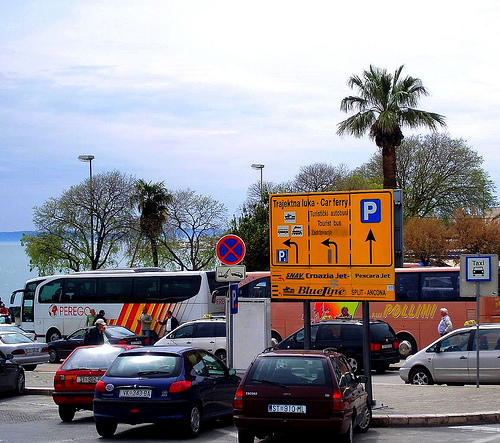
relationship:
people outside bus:
[67, 303, 186, 362] [9, 251, 231, 359]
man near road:
[77, 300, 118, 379] [0, 388, 473, 438]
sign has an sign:
[188, 220, 258, 270] [215, 232, 247, 264]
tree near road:
[129, 161, 184, 272] [0, 379, 494, 428]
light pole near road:
[39, 123, 134, 292] [19, 363, 463, 440]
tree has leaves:
[319, 46, 460, 236] [329, 66, 455, 145]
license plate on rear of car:
[240, 387, 329, 436] [220, 322, 383, 441]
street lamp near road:
[55, 134, 129, 304] [7, 346, 485, 441]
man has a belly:
[415, 292, 463, 351] [429, 270, 460, 369]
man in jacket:
[154, 305, 182, 341] [159, 315, 179, 330]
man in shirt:
[154, 305, 182, 341] [162, 315, 174, 335]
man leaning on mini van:
[328, 299, 359, 329] [254, 306, 414, 383]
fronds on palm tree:
[336, 59, 449, 158] [332, 51, 443, 275]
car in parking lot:
[224, 338, 416, 441] [0, 283, 498, 441]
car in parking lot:
[91, 342, 257, 440] [0, 283, 498, 441]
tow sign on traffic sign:
[213, 264, 246, 280] [214, 232, 246, 314]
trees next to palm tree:
[19, 158, 229, 286] [127, 179, 176, 279]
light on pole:
[244, 152, 269, 172] [243, 152, 277, 202]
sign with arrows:
[271, 187, 403, 301] [277, 228, 377, 272]